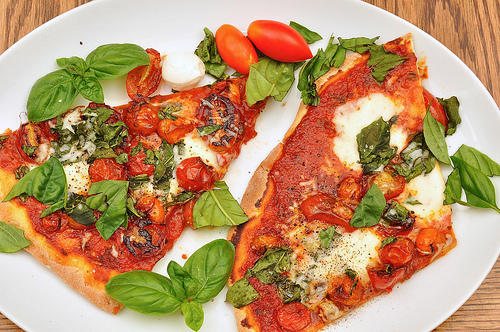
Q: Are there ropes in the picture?
A: No, there are no ropes.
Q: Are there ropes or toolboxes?
A: No, there are no ropes or toolboxes.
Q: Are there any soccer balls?
A: No, there are no soccer balls.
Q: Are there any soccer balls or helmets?
A: No, there are no soccer balls or helmets.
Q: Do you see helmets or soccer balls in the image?
A: No, there are no soccer balls or helmets.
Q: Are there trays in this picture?
A: No, there are no trays.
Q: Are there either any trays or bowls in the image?
A: No, there are no trays or bowls.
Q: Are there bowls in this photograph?
A: No, there are no bowls.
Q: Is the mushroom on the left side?
A: Yes, the mushroom is on the left of the image.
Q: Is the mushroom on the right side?
A: No, the mushroom is on the left of the image.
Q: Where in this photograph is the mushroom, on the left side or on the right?
A: The mushroom is on the left of the image.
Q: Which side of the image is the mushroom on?
A: The mushroom is on the left of the image.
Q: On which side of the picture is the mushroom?
A: The mushroom is on the left of the image.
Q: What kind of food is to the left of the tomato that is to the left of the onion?
A: The food is a mushroom.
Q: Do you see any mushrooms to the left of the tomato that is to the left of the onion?
A: Yes, there is a mushroom to the left of the tomato.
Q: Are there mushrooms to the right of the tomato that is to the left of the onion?
A: No, the mushroom is to the left of the tomato.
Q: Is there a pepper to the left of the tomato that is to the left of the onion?
A: No, there is a mushroom to the left of the tomato.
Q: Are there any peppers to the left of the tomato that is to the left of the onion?
A: No, there is a mushroom to the left of the tomato.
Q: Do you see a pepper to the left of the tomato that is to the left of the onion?
A: No, there is a mushroom to the left of the tomato.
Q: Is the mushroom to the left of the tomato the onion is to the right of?
A: Yes, the mushroom is to the left of the tomato.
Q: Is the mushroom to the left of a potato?
A: No, the mushroom is to the left of the tomato.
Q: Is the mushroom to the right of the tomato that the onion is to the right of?
A: No, the mushroom is to the left of the tomato.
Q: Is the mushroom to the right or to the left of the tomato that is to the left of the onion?
A: The mushroom is to the left of the tomato.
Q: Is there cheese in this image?
A: Yes, there is cheese.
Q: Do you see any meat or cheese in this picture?
A: Yes, there is cheese.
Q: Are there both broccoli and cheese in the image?
A: No, there is cheese but no broccoli.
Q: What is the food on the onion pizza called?
A: The food is cheese.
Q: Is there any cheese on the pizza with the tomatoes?
A: Yes, there is cheese on the pizza.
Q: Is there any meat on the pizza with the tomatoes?
A: No, there is cheese on the pizza.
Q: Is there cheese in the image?
A: Yes, there is cheese.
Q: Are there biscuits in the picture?
A: No, there are no biscuits.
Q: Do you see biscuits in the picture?
A: No, there are no biscuits.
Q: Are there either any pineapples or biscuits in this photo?
A: No, there are no biscuits or pineapples.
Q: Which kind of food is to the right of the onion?
A: The food is cheese.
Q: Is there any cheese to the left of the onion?
A: No, the cheese is to the right of the onion.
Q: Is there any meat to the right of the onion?
A: No, there is cheese to the right of the onion.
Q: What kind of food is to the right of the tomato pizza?
A: The food is cheese.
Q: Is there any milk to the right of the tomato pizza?
A: No, there is cheese to the right of the pizza.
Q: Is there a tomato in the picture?
A: Yes, there is a tomato.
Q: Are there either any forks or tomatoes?
A: Yes, there is a tomato.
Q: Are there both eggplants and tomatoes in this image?
A: No, there is a tomato but no eggplants.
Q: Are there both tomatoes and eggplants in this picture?
A: No, there is a tomato but no eggplants.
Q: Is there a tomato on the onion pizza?
A: Yes, there is a tomato on the pizza.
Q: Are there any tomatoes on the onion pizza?
A: Yes, there is a tomato on the pizza.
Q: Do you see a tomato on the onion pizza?
A: Yes, there is a tomato on the pizza.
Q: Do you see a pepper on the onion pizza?
A: No, there is a tomato on the pizza.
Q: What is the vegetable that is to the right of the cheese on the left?
A: The vegetable is a tomato.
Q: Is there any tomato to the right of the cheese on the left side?
A: Yes, there is a tomato to the right of the cheese.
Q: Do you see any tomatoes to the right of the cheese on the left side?
A: Yes, there is a tomato to the right of the cheese.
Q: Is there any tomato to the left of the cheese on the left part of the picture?
A: No, the tomato is to the right of the cheese.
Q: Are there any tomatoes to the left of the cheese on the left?
A: No, the tomato is to the right of the cheese.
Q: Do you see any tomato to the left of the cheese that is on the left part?
A: No, the tomato is to the right of the cheese.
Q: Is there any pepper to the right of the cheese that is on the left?
A: No, there is a tomato to the right of the cheese.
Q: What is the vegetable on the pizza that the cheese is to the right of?
A: The vegetable is a tomato.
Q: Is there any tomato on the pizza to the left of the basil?
A: Yes, there is a tomato on the pizza.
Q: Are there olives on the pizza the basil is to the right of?
A: No, there is a tomato on the pizza.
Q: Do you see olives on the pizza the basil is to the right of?
A: No, there is a tomato on the pizza.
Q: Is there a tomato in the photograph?
A: Yes, there are tomatoes.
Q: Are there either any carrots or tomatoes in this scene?
A: Yes, there are tomatoes.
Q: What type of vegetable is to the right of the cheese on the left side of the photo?
A: The vegetables are tomatoes.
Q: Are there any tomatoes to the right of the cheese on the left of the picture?
A: Yes, there are tomatoes to the right of the cheese.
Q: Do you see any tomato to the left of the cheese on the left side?
A: No, the tomatoes are to the right of the cheese.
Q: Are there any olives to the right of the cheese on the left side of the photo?
A: No, there are tomatoes to the right of the cheese.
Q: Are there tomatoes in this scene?
A: Yes, there are tomatoes.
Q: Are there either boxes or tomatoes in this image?
A: Yes, there are tomatoes.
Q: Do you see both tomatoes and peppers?
A: No, there are tomatoes but no peppers.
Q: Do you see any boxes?
A: No, there are no boxes.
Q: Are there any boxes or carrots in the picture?
A: No, there are no boxes or carrots.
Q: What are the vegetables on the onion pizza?
A: The vegetables are tomatoes.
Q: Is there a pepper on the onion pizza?
A: No, there are tomatoes on the pizza.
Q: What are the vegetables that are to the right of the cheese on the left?
A: The vegetables are tomatoes.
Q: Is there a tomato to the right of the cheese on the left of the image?
A: Yes, there are tomatoes to the right of the cheese.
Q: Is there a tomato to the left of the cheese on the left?
A: No, the tomatoes are to the right of the cheese.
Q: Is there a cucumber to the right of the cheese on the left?
A: No, there are tomatoes to the right of the cheese.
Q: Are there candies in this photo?
A: No, there are no candies.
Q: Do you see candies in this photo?
A: No, there are no candies.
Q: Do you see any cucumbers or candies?
A: No, there are no candies or cucumbers.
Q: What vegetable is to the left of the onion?
A: The vegetable is basil.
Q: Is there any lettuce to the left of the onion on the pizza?
A: No, there is basil to the left of the onion.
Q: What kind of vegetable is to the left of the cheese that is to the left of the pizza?
A: The vegetable is basil.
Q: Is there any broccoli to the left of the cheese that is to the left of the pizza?
A: No, there is basil to the left of the cheese.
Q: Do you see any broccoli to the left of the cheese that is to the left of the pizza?
A: No, there is basil to the left of the cheese.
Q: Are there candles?
A: No, there are no candles.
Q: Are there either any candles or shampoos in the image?
A: No, there are no candles or shampoos.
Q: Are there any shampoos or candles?
A: No, there are no candles or shampoos.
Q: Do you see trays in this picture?
A: No, there are no trays.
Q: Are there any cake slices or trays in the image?
A: No, there are no trays or cake slices.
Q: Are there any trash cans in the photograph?
A: No, there are no trash cans.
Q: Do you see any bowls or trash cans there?
A: No, there are no trash cans or bowls.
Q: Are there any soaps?
A: No, there are no soaps.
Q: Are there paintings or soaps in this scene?
A: No, there are no soaps or paintings.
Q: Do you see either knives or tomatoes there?
A: Yes, there is a tomato.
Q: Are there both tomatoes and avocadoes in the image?
A: No, there is a tomato but no avocadoes.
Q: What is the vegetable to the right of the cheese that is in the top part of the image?
A: The vegetable is a tomato.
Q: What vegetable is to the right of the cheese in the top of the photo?
A: The vegetable is a tomato.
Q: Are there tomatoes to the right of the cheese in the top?
A: Yes, there is a tomato to the right of the cheese.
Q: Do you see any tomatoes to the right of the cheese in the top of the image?
A: Yes, there is a tomato to the right of the cheese.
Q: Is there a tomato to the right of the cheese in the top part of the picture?
A: Yes, there is a tomato to the right of the cheese.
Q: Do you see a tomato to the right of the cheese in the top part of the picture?
A: Yes, there is a tomato to the right of the cheese.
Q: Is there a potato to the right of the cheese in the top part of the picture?
A: No, there is a tomato to the right of the cheese.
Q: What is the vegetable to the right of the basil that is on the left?
A: The vegetable is a tomato.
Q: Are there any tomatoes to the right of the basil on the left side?
A: Yes, there is a tomato to the right of the basil.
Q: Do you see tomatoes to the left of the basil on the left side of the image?
A: No, the tomato is to the right of the basil.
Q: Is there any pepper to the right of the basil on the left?
A: No, there is a tomato to the right of the basil.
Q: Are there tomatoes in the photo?
A: Yes, there is a tomato.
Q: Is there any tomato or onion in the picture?
A: Yes, there is a tomato.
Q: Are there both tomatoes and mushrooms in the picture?
A: Yes, there are both a tomato and mushrooms.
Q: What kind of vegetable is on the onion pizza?
A: The vegetable is a tomato.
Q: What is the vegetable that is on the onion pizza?
A: The vegetable is a tomato.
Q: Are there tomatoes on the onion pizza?
A: Yes, there is a tomato on the pizza.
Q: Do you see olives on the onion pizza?
A: No, there is a tomato on the pizza.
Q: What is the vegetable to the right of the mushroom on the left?
A: The vegetable is a tomato.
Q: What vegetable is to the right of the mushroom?
A: The vegetable is a tomato.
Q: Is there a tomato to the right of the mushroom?
A: Yes, there is a tomato to the right of the mushroom.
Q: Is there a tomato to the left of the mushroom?
A: No, the tomato is to the right of the mushroom.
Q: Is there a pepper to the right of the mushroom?
A: No, there is a tomato to the right of the mushroom.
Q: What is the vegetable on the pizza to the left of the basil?
A: The vegetable is a tomato.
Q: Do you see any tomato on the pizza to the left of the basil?
A: Yes, there is a tomato on the pizza.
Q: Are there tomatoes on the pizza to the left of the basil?
A: Yes, there is a tomato on the pizza.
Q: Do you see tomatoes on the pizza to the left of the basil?
A: Yes, there is a tomato on the pizza.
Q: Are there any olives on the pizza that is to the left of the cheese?
A: No, there is a tomato on the pizza.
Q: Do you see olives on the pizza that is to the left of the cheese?
A: No, there is a tomato on the pizza.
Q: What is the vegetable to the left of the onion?
A: The vegetable is a tomato.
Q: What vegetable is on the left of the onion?
A: The vegetable is a tomato.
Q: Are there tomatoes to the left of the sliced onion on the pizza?
A: Yes, there is a tomato to the left of the onion.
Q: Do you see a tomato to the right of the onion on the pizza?
A: No, the tomato is to the left of the onion.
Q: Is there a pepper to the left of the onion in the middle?
A: No, there is a tomato to the left of the onion.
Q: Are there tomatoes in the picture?
A: Yes, there are tomatoes.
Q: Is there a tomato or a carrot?
A: Yes, there are tomatoes.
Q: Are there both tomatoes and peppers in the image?
A: No, there are tomatoes but no peppers.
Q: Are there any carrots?
A: No, there are no carrots.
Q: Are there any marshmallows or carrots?
A: No, there are no carrots or marshmallows.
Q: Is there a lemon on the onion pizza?
A: No, there are tomatoes on the pizza.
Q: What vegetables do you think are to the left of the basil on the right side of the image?
A: The vegetables are tomatoes.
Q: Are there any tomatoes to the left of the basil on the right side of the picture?
A: Yes, there are tomatoes to the left of the basil.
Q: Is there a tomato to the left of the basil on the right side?
A: Yes, there are tomatoes to the left of the basil.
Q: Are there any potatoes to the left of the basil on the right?
A: No, there are tomatoes to the left of the basil.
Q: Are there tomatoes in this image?
A: Yes, there are tomatoes.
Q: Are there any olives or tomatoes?
A: Yes, there are tomatoes.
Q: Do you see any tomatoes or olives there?
A: Yes, there are tomatoes.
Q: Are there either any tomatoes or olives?
A: Yes, there are tomatoes.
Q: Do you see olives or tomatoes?
A: Yes, there are tomatoes.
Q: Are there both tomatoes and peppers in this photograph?
A: No, there are tomatoes but no peppers.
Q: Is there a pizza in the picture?
A: Yes, there is a pizza.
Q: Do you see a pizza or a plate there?
A: Yes, there is a pizza.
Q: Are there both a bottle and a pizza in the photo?
A: No, there is a pizza but no bottles.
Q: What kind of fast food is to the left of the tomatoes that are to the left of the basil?
A: The food is a pizza.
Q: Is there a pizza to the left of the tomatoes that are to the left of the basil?
A: Yes, there is a pizza to the left of the tomatoes.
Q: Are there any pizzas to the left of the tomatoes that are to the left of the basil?
A: Yes, there is a pizza to the left of the tomatoes.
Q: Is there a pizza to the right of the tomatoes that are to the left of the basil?
A: No, the pizza is to the left of the tomatoes.